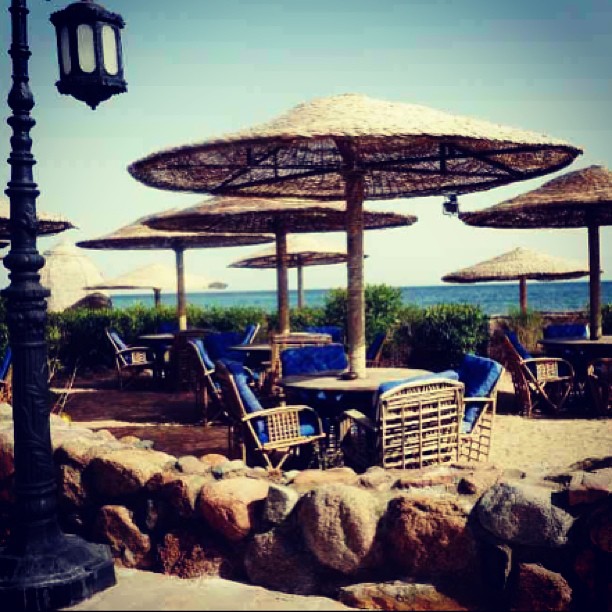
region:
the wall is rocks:
[178, 455, 396, 572]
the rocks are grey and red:
[155, 461, 427, 581]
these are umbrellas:
[176, 118, 424, 312]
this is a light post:
[12, 36, 204, 571]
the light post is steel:
[0, 125, 94, 462]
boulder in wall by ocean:
[300, 481, 377, 571]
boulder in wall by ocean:
[383, 486, 464, 571]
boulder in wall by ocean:
[465, 473, 561, 552]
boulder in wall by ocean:
[193, 467, 268, 535]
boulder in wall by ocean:
[259, 480, 298, 522]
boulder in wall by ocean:
[147, 467, 199, 509]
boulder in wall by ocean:
[102, 499, 151, 565]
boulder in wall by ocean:
[82, 451, 157, 494]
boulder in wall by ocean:
[295, 459, 357, 487]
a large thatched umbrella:
[121, 93, 579, 198]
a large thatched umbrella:
[144, 191, 415, 233]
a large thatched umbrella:
[75, 207, 272, 248]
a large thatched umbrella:
[228, 231, 366, 266]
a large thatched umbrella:
[438, 243, 598, 277]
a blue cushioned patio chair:
[210, 358, 321, 468]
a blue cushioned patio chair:
[430, 352, 502, 459]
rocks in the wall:
[296, 472, 481, 577]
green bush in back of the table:
[401, 294, 486, 357]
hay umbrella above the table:
[117, 97, 580, 193]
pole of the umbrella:
[335, 181, 374, 375]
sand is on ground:
[4, 409, 605, 608]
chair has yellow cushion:
[222, 368, 329, 474]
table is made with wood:
[264, 365, 471, 470]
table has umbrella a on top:
[124, 89, 584, 476]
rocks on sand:
[8, 409, 605, 603]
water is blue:
[91, 275, 606, 320]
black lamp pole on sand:
[1, 2, 353, 608]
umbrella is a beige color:
[121, 85, 589, 386]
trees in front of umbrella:
[33, 240, 563, 409]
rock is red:
[361, 493, 473, 591]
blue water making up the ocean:
[107, 280, 610, 310]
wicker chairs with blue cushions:
[1, 314, 603, 472]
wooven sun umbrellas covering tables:
[0, 92, 610, 284]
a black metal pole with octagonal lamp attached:
[0, 0, 132, 611]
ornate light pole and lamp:
[0, 0, 127, 603]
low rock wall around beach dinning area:
[3, 420, 610, 609]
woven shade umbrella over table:
[125, 94, 578, 375]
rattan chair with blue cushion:
[344, 374, 466, 476]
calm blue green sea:
[97, 279, 610, 317]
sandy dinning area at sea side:
[19, 375, 610, 493]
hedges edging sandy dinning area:
[51, 286, 486, 362]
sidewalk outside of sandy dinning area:
[33, 559, 414, 609]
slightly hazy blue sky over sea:
[4, 5, 609, 276]